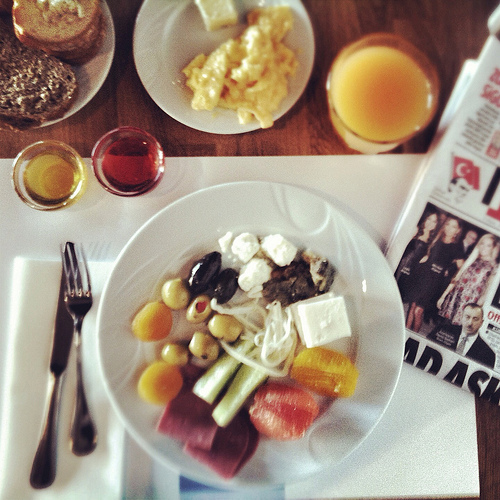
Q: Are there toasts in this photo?
A: Yes, there is a toast.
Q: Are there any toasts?
A: Yes, there is a toast.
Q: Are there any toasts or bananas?
A: Yes, there is a toast.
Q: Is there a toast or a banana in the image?
A: Yes, there is a toast.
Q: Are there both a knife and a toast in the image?
A: Yes, there are both a toast and a knife.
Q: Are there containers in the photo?
A: No, there are no containers.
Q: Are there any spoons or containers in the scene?
A: No, there are no containers or spoons.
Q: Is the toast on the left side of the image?
A: Yes, the toast is on the left of the image.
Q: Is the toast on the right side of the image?
A: No, the toast is on the left of the image.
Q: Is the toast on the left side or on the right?
A: The toast is on the left of the image.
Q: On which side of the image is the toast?
A: The toast is on the left of the image.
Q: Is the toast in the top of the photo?
A: Yes, the toast is in the top of the image.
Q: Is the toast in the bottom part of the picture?
A: No, the toast is in the top of the image.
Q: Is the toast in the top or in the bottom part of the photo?
A: The toast is in the top of the image.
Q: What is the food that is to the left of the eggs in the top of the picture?
A: The food is a toast.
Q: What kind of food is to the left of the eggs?
A: The food is a toast.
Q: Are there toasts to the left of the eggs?
A: Yes, there is a toast to the left of the eggs.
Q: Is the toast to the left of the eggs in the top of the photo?
A: Yes, the toast is to the left of the eggs.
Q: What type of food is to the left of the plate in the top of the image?
A: The food is a toast.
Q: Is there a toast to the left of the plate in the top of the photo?
A: Yes, there is a toast to the left of the plate.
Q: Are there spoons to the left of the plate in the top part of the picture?
A: No, there is a toast to the left of the plate.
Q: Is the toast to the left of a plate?
A: Yes, the toast is to the left of a plate.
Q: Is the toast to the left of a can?
A: No, the toast is to the left of a plate.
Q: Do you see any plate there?
A: Yes, there is a plate.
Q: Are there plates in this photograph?
A: Yes, there is a plate.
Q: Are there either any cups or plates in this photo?
A: Yes, there is a plate.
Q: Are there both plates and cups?
A: Yes, there are both a plate and a cup.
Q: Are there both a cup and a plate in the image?
A: Yes, there are both a plate and a cup.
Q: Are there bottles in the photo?
A: No, there are no bottles.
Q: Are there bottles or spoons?
A: No, there are no bottles or spoons.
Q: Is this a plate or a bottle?
A: This is a plate.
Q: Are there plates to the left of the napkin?
A: No, the plate is to the right of the napkin.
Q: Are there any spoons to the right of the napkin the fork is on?
A: No, there is a plate to the right of the napkin.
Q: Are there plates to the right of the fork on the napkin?
A: Yes, there is a plate to the right of the fork.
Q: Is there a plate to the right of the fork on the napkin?
A: Yes, there is a plate to the right of the fork.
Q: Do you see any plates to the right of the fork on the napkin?
A: Yes, there is a plate to the right of the fork.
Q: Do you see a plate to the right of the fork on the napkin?
A: Yes, there is a plate to the right of the fork.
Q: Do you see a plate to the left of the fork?
A: No, the plate is to the right of the fork.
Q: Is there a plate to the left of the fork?
A: No, the plate is to the right of the fork.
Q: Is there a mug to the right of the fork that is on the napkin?
A: No, there is a plate to the right of the fork.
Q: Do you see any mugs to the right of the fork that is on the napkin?
A: No, there is a plate to the right of the fork.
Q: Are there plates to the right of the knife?
A: Yes, there is a plate to the right of the knife.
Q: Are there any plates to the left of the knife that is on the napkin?
A: No, the plate is to the right of the knife.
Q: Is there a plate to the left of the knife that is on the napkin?
A: No, the plate is to the right of the knife.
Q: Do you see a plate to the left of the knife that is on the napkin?
A: No, the plate is to the right of the knife.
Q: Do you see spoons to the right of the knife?
A: No, there is a plate to the right of the knife.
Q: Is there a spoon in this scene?
A: No, there are no spoons.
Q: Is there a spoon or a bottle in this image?
A: No, there are no spoons or bottles.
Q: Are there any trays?
A: No, there are no trays.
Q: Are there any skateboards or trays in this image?
A: No, there are no trays or skateboards.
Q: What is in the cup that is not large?
A: The liquid is in the cup.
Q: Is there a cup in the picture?
A: Yes, there is a cup.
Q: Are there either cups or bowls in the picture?
A: Yes, there is a cup.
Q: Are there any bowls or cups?
A: Yes, there is a cup.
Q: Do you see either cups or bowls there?
A: Yes, there is a cup.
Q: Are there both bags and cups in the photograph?
A: No, there is a cup but no bags.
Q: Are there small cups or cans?
A: Yes, there is a small cup.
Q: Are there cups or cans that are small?
A: Yes, the cup is small.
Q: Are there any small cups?
A: Yes, there is a small cup.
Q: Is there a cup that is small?
A: Yes, there is a cup that is small.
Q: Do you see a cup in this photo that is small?
A: Yes, there is a cup that is small.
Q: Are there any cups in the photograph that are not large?
A: Yes, there is a small cup.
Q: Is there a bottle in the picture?
A: No, there are no bottles.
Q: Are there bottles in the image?
A: No, there are no bottles.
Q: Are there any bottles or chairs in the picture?
A: No, there are no bottles or chairs.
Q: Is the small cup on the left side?
A: Yes, the cup is on the left of the image.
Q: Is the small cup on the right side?
A: No, the cup is on the left of the image.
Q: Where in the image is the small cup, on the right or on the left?
A: The cup is on the left of the image.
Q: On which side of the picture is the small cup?
A: The cup is on the left of the image.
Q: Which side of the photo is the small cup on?
A: The cup is on the left of the image.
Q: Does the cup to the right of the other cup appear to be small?
A: Yes, the cup is small.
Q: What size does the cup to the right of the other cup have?
A: The cup has small size.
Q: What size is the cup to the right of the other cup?
A: The cup is small.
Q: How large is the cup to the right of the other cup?
A: The cup is small.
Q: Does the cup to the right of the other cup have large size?
A: No, the cup is small.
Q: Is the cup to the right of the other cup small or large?
A: The cup is small.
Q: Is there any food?
A: Yes, there is food.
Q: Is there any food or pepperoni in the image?
A: Yes, there is food.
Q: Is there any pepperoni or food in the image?
A: Yes, there is food.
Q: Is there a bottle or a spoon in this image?
A: No, there are no bottles or spoons.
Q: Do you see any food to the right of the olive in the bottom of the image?
A: Yes, there is food to the right of the olive.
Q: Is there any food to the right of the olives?
A: Yes, there is food to the right of the olives.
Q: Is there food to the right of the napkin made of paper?
A: Yes, there is food to the right of the napkin.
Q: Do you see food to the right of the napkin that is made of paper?
A: Yes, there is food to the right of the napkin.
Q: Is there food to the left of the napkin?
A: No, the food is to the right of the napkin.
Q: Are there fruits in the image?
A: Yes, there is a fruit.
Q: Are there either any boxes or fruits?
A: Yes, there is a fruit.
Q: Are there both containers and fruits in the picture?
A: No, there is a fruit but no containers.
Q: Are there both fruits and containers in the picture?
A: No, there is a fruit but no containers.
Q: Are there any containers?
A: No, there are no containers.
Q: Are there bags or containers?
A: No, there are no containers or bags.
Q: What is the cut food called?
A: The food is a fruit.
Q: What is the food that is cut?
A: The food is a fruit.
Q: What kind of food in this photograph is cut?
A: The food is a fruit.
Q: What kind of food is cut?
A: The food is a fruit.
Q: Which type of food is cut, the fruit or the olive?
A: The fruit is cut.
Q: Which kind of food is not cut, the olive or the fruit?
A: The olive is not cut.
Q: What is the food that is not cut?
A: The food is an olive.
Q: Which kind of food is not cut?
A: The food is an olive.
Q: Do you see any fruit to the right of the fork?
A: Yes, there is a fruit to the right of the fork.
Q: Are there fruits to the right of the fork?
A: Yes, there is a fruit to the right of the fork.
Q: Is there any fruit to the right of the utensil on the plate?
A: Yes, there is a fruit to the right of the fork.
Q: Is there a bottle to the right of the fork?
A: No, there is a fruit to the right of the fork.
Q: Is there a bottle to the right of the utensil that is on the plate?
A: No, there is a fruit to the right of the fork.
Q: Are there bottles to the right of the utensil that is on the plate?
A: No, there is a fruit to the right of the fork.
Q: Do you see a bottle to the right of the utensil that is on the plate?
A: No, there is a fruit to the right of the fork.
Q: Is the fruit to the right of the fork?
A: Yes, the fruit is to the right of the fork.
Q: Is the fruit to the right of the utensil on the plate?
A: Yes, the fruit is to the right of the fork.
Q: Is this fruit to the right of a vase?
A: No, the fruit is to the right of the fork.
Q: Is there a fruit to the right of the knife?
A: Yes, there is a fruit to the right of the knife.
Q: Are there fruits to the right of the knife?
A: Yes, there is a fruit to the right of the knife.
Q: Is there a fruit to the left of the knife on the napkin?
A: No, the fruit is to the right of the knife.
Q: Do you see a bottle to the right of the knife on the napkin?
A: No, there is a fruit to the right of the knife.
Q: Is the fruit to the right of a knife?
A: Yes, the fruit is to the right of a knife.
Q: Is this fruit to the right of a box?
A: No, the fruit is to the right of a knife.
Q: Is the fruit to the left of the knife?
A: No, the fruit is to the right of the knife.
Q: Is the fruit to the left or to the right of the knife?
A: The fruit is to the right of the knife.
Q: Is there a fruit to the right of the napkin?
A: Yes, there is a fruit to the right of the napkin.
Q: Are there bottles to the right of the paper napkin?
A: No, there is a fruit to the right of the napkin.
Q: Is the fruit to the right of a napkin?
A: Yes, the fruit is to the right of a napkin.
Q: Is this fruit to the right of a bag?
A: No, the fruit is to the right of a napkin.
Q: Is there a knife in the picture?
A: Yes, there is a knife.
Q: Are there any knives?
A: Yes, there is a knife.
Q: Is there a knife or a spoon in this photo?
A: Yes, there is a knife.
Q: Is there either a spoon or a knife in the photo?
A: Yes, there is a knife.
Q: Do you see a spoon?
A: No, there are no spoons.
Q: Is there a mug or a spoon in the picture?
A: No, there are no spoons or mugs.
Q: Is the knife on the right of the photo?
A: No, the knife is on the left of the image.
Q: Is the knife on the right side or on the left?
A: The knife is on the left of the image.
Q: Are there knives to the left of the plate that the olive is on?
A: Yes, there is a knife to the left of the plate.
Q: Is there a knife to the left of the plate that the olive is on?
A: Yes, there is a knife to the left of the plate.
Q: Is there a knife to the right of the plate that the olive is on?
A: No, the knife is to the left of the plate.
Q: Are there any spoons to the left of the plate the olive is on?
A: No, there is a knife to the left of the plate.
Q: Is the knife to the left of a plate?
A: Yes, the knife is to the left of a plate.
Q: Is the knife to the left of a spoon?
A: No, the knife is to the left of a plate.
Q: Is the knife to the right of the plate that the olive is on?
A: No, the knife is to the left of the plate.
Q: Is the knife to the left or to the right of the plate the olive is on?
A: The knife is to the left of the plate.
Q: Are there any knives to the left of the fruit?
A: Yes, there is a knife to the left of the fruit.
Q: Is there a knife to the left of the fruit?
A: Yes, there is a knife to the left of the fruit.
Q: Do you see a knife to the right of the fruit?
A: No, the knife is to the left of the fruit.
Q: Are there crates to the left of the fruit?
A: No, there is a knife to the left of the fruit.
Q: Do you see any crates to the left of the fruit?
A: No, there is a knife to the left of the fruit.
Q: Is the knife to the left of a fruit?
A: Yes, the knife is to the left of a fruit.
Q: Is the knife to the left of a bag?
A: No, the knife is to the left of a fruit.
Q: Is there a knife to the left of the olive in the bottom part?
A: Yes, there is a knife to the left of the olive.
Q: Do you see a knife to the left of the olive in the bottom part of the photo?
A: Yes, there is a knife to the left of the olive.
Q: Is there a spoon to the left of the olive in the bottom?
A: No, there is a knife to the left of the olive.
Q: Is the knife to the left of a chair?
A: No, the knife is to the left of an olive.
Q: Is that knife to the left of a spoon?
A: No, the knife is to the left of an olive.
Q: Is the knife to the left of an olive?
A: Yes, the knife is to the left of an olive.